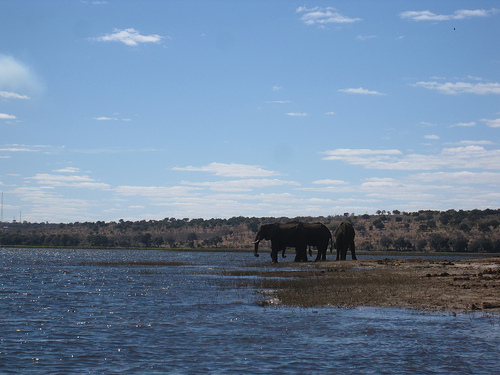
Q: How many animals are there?
A: Two.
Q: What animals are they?
A: Elephants.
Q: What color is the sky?
A: Blue.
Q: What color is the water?
A: Dark blue.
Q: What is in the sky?
A: Clouds.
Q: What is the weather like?
A: Sunny.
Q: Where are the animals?
A: By the water.